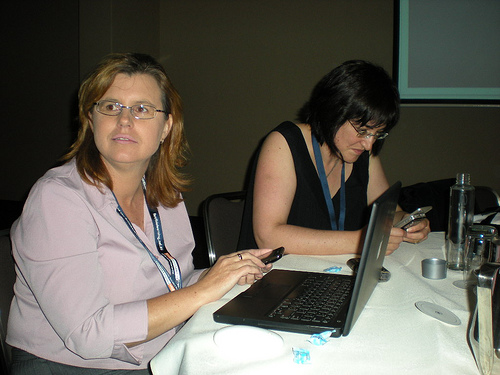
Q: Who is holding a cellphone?
A: Both women in picture.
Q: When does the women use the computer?
A: Photo doesn't suggest a time.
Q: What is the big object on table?
A: A laptop computer.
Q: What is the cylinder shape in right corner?
A: A bottle of water.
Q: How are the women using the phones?
A: With hands and fingers.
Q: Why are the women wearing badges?
A: Women are part of a conference.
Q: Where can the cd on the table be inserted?
A: Inside the laptop computer.